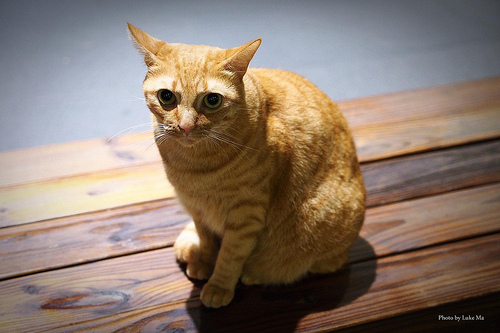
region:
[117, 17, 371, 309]
yellow tiger cat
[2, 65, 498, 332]
wood bench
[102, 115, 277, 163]
whiskers on a cats face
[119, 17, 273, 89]
cat ears pointed slightly outwards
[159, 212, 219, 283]
cat tail curled around front paw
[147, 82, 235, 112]
cat eyes with large dilated pupils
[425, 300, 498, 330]
photographers water mark on photo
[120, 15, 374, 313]
cat in sitting position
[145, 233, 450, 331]
shadow of cat sitting on bench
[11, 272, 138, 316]
knot in piece of wood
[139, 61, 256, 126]
Cat has large eyes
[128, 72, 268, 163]
Cat has light colored eyes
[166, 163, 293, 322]
Cat is orange striped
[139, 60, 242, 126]
Cat looks nervous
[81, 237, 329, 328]
Cat sitting on bench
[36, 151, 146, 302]
Bench is made of wood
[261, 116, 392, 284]
Cat is sitting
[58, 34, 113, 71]
Wall is light blue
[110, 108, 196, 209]
Cat has white whiskers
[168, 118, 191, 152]
end of cat's nose is pink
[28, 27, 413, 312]
a cat sitting outside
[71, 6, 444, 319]
a cat sitting on a bench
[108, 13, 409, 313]
a cat looking at the camera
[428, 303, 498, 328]
the photographers company logo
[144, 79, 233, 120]
a pair of dark eyes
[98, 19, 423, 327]
a brown and white cat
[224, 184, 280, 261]
some striped fur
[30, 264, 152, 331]
a knot in the wood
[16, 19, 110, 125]
light grey flooring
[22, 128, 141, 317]
a few rows of wood planks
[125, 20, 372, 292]
this is a cat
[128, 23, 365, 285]
the cat is brown in color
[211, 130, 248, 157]
this is a fur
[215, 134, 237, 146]
the fur are white in color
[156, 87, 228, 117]
the eyes of the cat are wide open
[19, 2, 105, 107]
this is a wall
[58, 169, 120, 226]
this is a table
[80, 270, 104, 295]
the table is wooden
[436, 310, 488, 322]
this is a writing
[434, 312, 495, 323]
the wrings are in white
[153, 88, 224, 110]
the eyes are wide open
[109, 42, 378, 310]
the cat is sitted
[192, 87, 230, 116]
the eye is big in size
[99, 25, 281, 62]
the ears are wide apart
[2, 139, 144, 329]
this is a table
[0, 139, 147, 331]
the table is wooden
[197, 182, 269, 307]
the front limb is in front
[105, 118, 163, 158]
these are the cats whiskers